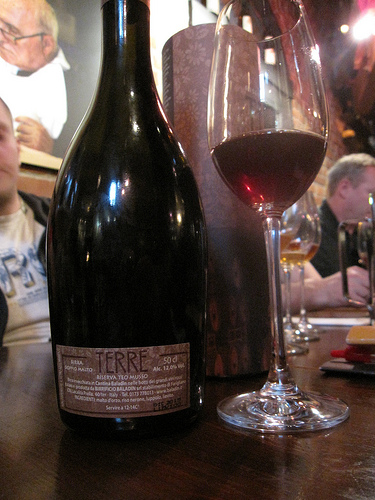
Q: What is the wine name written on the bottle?
A: TERRE.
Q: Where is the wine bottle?
A: On the table.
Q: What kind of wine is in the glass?
A: Red.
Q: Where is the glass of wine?
A: Next to the bottle.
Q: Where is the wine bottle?
A: Left from the glass.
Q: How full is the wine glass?
A: A third.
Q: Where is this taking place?
A: In a restaurant.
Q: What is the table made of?
A: Wood.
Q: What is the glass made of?
A: Glass.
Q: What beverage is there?
A: Wine.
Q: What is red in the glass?
A: Wine.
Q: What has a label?
A: Bottle.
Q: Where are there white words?
A: Label.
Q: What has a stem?
A: Wine glass.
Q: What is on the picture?
A: Man in bib.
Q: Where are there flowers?
A: Brown cylinder.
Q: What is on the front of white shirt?
A: Letters.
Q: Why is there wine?
A: To drink.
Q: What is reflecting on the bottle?
A: Lights.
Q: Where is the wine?
A: In the glass.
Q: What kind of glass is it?
A: Wine glass.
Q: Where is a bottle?
A: On the table.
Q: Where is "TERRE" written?
A: On a label.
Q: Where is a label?
A: On the bottle.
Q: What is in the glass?
A: Wine.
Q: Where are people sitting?
A: At a table.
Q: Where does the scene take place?
A: At a restaurant.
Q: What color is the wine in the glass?
A: Red.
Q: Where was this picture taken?
A: At the restaurant.